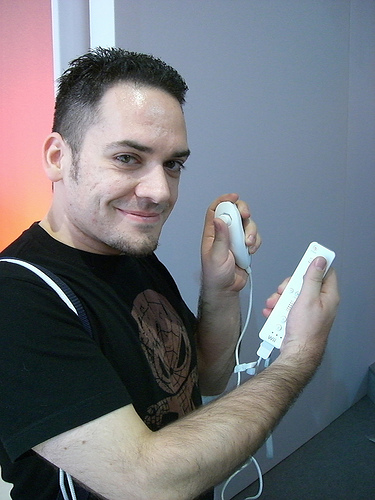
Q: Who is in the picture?
A: A man.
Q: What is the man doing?
A: Holding a device.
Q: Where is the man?
A: Standing in the hallway.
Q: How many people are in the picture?
A: One.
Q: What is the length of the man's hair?
A: Short.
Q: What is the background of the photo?
A: A wall.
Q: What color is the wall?
A: White.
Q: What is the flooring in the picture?
A: Carpet.